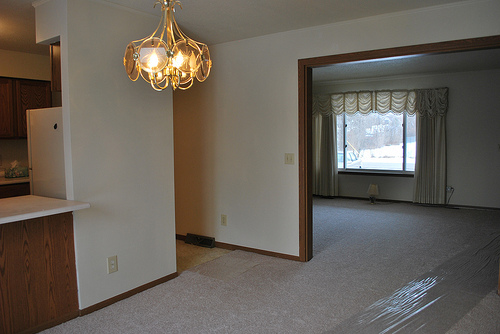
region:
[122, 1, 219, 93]
gold-toned chandelier light in dining area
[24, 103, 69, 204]
white refrigerator in kitchen area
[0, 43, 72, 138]
wooden cabinets in kitchen area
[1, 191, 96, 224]
white counter for eating bar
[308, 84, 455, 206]
drapes on picture window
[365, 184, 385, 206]
small lamp sitting beneath window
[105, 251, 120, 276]
electrical outlet in wall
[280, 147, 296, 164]
light switch on wall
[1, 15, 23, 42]
glare from kitchen light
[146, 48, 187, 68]
light bulbs in chandelier fixture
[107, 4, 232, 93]
golden chandelier hanging on roof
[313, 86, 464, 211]
white curtains against white wall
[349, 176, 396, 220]
small lamp on carpet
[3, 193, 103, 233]
white counter top supported by wooden frame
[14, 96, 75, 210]
white refrigerator reflecting light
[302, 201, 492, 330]
plastic lining on carpet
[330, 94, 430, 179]
green shrubs and grass through window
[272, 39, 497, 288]
wooden frame surrounding entrance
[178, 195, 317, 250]
black object resting against white wall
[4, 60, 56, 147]
wooden cabinets against white wall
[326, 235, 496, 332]
strip of plastic on the floor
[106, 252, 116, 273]
outlet cover on the wall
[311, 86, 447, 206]
sheer curtain on the window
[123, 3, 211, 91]
chandelier with the lights on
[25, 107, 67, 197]
side of a fridge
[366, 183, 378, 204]
lamp on the floor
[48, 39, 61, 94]
cupboard above the fridge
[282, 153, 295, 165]
white light switch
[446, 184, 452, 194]
outlet with a cord plugged in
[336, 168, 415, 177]
shelf below the window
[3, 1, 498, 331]
interior of empty house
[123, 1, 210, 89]
light hanging from ceiling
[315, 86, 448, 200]
curtains on sides of window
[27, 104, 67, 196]
side of white refrigerator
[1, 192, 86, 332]
white counter top over wood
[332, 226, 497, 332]
plastic cover on carpet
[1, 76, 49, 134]
wood cupboards in kitchen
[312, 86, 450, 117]
valance hanging over window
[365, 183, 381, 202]
lamp sitting on floor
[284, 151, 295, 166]
light switch on wall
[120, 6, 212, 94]
chandelier hanging in the roof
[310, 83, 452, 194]
white curtains in the window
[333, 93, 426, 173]
white window in the back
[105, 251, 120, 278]
whie plug in white wall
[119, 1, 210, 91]
golden chandelier with lights on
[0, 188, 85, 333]
kitchen counter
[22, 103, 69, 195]
white fridge behind white wall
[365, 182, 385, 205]
little lamp in the floor under the window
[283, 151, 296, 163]
white switch in the wall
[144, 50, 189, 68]
light bulbs in the chandelier